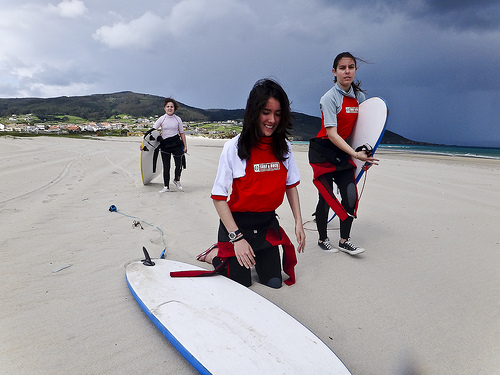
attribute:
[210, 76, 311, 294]
girl — kneeling, surfer, ready, going, young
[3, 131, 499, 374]
sand — brown, white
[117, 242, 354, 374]
surfboard — blue, white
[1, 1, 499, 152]
sky — dark, cloudy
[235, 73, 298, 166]
hair — black, long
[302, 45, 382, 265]
girl — going, young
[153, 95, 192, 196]
woman — walking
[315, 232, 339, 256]
shoes — black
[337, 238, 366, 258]
shoes — black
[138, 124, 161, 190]
surfboard — yellow, white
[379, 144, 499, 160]
waves — coming, rolling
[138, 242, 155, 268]
fin — small, black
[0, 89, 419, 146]
mountains — rocky, black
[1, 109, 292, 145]
town — small